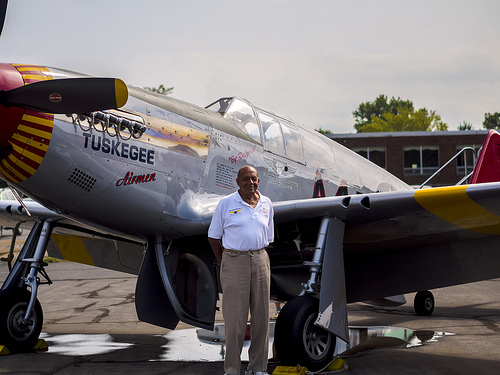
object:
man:
[206, 166, 275, 375]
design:
[228, 207, 241, 215]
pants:
[219, 248, 272, 374]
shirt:
[208, 188, 276, 252]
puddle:
[160, 327, 234, 365]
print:
[116, 171, 157, 187]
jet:
[0, 54, 498, 371]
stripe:
[413, 184, 500, 229]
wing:
[217, 180, 500, 305]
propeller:
[0, 76, 130, 112]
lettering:
[82, 132, 155, 165]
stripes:
[0, 110, 55, 183]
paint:
[423, 189, 465, 211]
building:
[319, 130, 499, 190]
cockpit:
[109, 77, 271, 130]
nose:
[1, 61, 25, 90]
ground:
[75, 279, 153, 349]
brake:
[277, 353, 341, 374]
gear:
[272, 289, 350, 372]